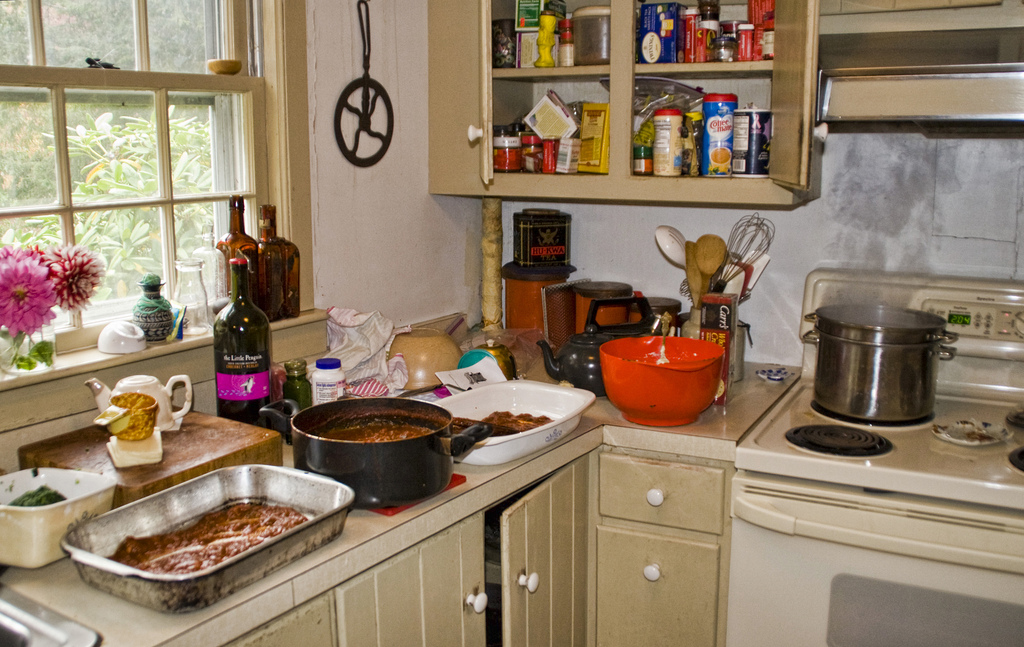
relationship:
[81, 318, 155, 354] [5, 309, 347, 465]
timer on ledge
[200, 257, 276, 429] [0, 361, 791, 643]
bottle on counter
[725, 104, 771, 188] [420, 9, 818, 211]
container in cabinet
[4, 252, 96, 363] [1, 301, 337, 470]
flowers on ledge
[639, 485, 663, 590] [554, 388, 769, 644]
handles on cabinets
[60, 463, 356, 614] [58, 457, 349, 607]
dish inside pan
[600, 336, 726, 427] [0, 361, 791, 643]
bowl on counter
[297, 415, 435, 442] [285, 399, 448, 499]
food in pot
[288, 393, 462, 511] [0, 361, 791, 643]
pot on counter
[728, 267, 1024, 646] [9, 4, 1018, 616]
oven in kitchen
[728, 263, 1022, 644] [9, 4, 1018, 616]
oven in kitchen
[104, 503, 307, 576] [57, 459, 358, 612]
food in dish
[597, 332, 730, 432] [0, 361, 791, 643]
bowl on counter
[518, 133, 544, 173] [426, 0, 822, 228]
spice in cabinet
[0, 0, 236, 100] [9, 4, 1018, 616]
window in kitchen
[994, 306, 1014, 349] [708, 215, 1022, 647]
lights on stove